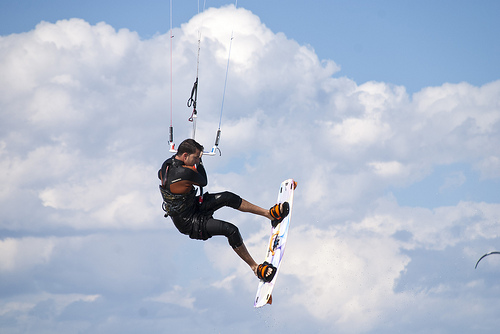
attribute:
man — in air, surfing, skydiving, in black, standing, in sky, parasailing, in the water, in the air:
[160, 143, 288, 278]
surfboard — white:
[249, 178, 296, 306]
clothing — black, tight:
[155, 165, 240, 245]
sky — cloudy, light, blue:
[5, 1, 157, 331]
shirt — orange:
[169, 180, 194, 195]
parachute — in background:
[474, 251, 499, 268]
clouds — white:
[1, 20, 496, 156]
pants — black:
[198, 195, 243, 262]